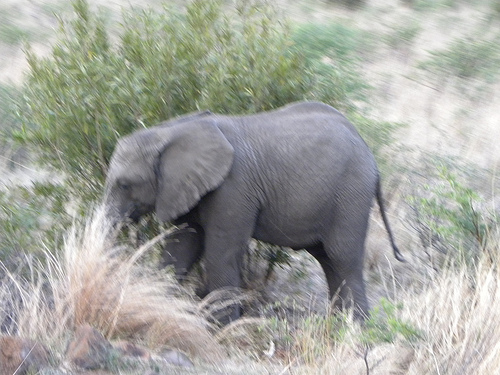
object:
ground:
[2, 271, 499, 369]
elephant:
[93, 89, 415, 329]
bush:
[0, 198, 262, 374]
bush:
[0, 0, 150, 191]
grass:
[0, 172, 500, 373]